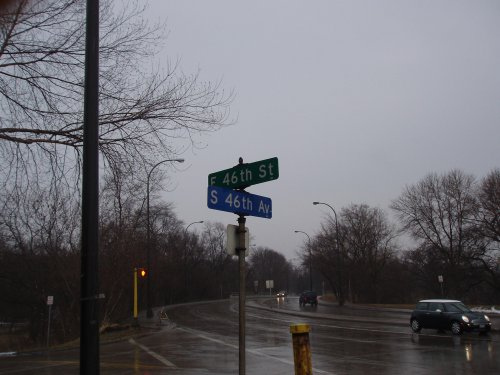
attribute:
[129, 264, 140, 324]
pole — yellow, tall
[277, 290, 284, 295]
lights — on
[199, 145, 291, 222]
signs — green and blue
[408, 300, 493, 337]
car — mini cooper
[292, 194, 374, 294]
posts — metal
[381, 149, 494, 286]
trees — bare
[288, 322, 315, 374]
pole — yellow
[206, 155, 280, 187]
street sign — green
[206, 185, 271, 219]
street sign — white letters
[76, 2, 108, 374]
pole — tall, dark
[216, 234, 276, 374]
pole — metal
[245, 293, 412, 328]
medium — concrete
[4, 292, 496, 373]
street — green and white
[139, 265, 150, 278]
lamp — illuminated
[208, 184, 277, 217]
sign — green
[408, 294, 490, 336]
cooper — black, white roof, mini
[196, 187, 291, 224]
sign — green, white letters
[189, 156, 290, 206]
sign — white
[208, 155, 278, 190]
sign — green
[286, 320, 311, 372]
post — yellow, rusted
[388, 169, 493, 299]
trees — bare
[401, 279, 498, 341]
vehicle — black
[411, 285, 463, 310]
roof — white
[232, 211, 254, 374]
post — metal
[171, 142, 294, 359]
pole — yellow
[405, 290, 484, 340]
vehicle — black